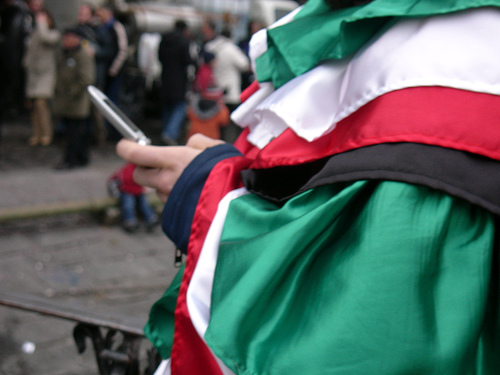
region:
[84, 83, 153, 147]
silver phone in hand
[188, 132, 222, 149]
thumb is bent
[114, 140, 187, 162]
index finger next to cell phone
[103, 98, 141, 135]
dark screen on cell phone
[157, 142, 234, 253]
blue sleeve next to hand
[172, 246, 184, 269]
metal zipper pull below sleeve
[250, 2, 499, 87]
green fabric ruffle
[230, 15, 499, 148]
silky white fabric ruffle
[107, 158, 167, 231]
person sitting on curb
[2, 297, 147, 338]
metal railing beneath cell phone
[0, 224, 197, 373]
a roughly paved road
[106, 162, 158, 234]
child sits to wait on a curb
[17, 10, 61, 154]
lady wearing light beige skirt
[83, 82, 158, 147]
flip top cell phone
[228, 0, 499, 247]
ruffled neck on a clown suit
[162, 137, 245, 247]
navy blue cuff on sleeve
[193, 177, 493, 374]
top layer of sleeve is green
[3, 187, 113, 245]
crub along the street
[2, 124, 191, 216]
the cement sidewalk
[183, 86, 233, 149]
an orange jacket with grey and black hood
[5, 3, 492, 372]
person holding cell phone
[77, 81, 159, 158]
cell phone is silver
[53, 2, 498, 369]
the coat is green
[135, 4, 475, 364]
the coat is red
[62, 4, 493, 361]
the coat is white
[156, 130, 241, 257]
the sleeve is blue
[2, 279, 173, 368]
the fence is metal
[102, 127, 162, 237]
a child sitting on the curb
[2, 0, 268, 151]
a crowd behind the cell phone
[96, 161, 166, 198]
red shirt on the boy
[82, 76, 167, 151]
grey plastic cell phone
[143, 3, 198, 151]
person on the street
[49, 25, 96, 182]
person on the street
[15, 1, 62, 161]
person on the street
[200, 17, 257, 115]
person on the street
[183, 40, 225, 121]
person on the street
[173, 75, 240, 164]
person on the street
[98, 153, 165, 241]
person on the street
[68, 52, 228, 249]
hand holding a cell phone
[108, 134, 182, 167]
finger of a person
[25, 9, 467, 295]
this person is using a cell phone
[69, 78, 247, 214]
they might be making a telephone call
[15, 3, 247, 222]
the people in the background are blurry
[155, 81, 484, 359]
this clothing has multiple colors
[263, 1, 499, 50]
the top part of the collar is green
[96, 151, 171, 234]
there is a child sitting on the curb\\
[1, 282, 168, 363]
this is some kind of rail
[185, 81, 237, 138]
this person has on an orange coat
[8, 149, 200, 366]
these people are standing on the street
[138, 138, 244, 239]
this person has on a black shirt underneath the others